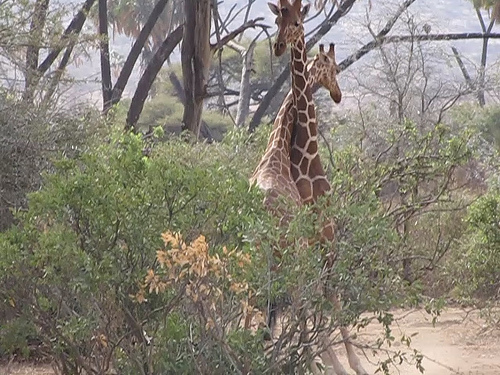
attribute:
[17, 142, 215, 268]
leaves — green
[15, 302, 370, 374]
branches — brown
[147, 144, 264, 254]
leaves — green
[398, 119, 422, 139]
leaf — green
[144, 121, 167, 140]
leaf — green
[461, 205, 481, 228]
leaf — green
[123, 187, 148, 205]
leaf — green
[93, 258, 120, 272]
leaf — green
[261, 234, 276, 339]
branch — brown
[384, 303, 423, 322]
branch — brown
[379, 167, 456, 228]
branch — brown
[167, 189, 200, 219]
branch — brown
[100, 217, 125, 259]
branch — brown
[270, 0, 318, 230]
giraffe — big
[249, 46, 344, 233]
giraffe — big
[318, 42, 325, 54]
horn — small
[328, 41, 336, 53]
horn — small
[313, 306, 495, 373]
ground — sandy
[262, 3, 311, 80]
giraffe — spotted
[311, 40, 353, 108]
giraffe — spotted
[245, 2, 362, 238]
giraffe — spotted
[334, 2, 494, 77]
tree — leaning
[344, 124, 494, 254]
leaves — green 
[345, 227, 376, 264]
leaves — green 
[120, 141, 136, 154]
leaves — green 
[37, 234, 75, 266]
leaves — green 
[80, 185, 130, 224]
leaves — green 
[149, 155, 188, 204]
leaves — green 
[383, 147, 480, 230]
branches — brown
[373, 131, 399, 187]
branches — brown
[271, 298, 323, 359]
branches — brown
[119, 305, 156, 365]
branches — brown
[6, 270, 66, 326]
branches — brown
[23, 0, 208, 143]
trees — bare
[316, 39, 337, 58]
ears — brown, spotted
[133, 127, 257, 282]
branches — brown 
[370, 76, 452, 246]
branches — brown 